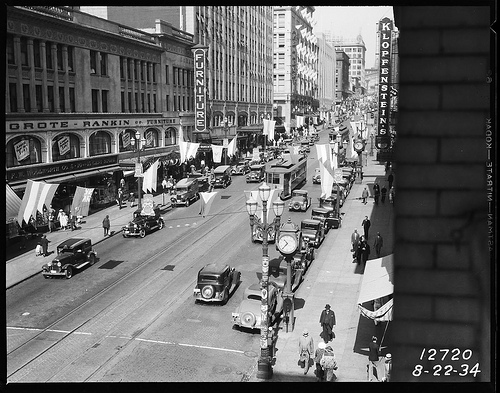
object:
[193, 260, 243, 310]
vehicle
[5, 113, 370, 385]
road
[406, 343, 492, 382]
date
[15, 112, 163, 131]
sign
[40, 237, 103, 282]
car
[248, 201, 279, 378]
post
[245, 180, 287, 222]
lamp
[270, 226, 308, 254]
clock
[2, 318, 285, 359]
line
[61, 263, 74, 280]
tire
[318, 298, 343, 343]
man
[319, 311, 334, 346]
suit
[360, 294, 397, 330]
flag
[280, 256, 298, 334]
pole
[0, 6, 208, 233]
building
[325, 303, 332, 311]
hat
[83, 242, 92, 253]
window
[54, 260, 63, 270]
headlight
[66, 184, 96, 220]
flag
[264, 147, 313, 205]
trolley